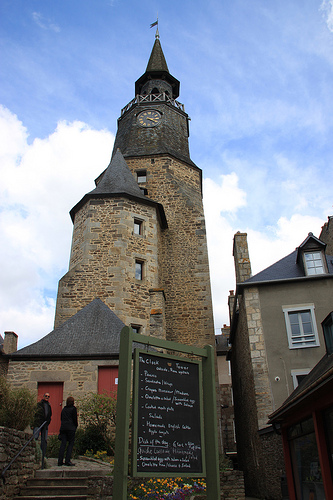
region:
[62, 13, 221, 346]
an old stone clock tower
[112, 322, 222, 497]
a sign made of wood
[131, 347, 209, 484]
a chalboard sign with writing on it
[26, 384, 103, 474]
people standing in front of a door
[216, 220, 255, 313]
two chimneys on a buidling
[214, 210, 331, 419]
a house with two chimneys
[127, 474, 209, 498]
colored flowers planted together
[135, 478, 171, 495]
yellow flowers under the sign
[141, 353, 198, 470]
white writing on a chalkboard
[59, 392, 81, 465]
a woman dressed in black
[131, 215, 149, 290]
Windows in a tower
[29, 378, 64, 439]
a red door in a building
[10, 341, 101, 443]
a building made of rock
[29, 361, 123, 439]
two red doors ina building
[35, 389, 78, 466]
a man and woman standing in front of a red door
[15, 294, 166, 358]
a pointed roof on a building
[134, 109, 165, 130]
the face of a clock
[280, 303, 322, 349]
a window on a building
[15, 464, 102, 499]
steps in front of a building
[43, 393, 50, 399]
a man wearing glasses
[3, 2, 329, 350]
blue sky with thick and faint clouds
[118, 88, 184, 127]
flag flying on top of pointed tower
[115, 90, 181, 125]
black clock with gold letters under terrace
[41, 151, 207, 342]
stone buildings with a few narrow windows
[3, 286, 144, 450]
dark triangular roof over stone building with red door and windows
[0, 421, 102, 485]
stone wall next to steps leading to landing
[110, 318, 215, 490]
green frame around blackboard with written menu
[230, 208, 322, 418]
gray and stone building with white windows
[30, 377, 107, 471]
man and woman outside of closed red door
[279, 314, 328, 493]
small red building with dark roof and windows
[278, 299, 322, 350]
window on a building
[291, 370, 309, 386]
window on a building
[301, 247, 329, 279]
window on a building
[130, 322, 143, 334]
window on a building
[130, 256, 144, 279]
window on a building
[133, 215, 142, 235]
window on a building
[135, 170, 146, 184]
window on a building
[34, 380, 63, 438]
red door on a building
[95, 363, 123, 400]
red door on a building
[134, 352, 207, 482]
black chalkboard sign outdoors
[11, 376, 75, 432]
the head of a man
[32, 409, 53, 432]
the arm of a man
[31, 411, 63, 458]
the leg of a man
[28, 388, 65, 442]
a man wearing a shirt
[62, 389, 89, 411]
the head of a woman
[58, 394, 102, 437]
the arm of a woman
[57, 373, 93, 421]
the back of a woman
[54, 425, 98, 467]
the legs of a woman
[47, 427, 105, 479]
the feet of a woman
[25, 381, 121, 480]
a woman near a building